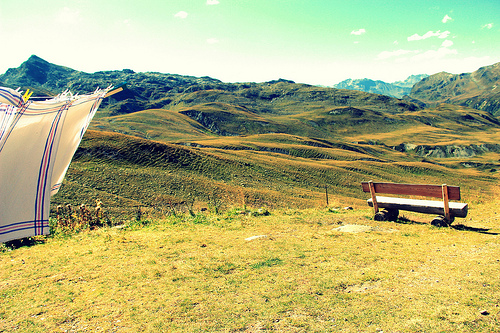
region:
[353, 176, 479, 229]
Wood bench in the field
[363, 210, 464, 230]
Wheels of wood bench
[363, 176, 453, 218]
Stick Two sticks holding back of bench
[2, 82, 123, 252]
Blanket holding from a string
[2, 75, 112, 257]
Blanket has red and blue stripes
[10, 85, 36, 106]
Yellow clothespin holding the blanket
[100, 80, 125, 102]
Brown clothespin holding the blanket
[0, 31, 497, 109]
Mountains in the background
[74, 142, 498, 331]
Green grass in the field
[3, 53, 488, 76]
Part of the sky is white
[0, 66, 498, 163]
grassy mountains in the background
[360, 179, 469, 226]
bench is made of wood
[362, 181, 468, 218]
bench in middle of grassy field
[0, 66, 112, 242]
cloths hanging from clothing line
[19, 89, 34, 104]
yellow clothing pin on line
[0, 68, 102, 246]
cloths are red, white and blue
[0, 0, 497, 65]
sky appear to be green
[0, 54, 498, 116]
mountains covered in moss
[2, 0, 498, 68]
sky is partly cloudy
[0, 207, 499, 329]
parched field of grass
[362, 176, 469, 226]
wooden bench sitting in grass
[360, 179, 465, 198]
back rest of wooden bench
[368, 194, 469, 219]
seat of wooden bench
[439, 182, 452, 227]
right back support on bench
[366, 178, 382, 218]
left back support of bench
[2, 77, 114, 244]
laundry hanging on a line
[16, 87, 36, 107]
yellow clothes pin on laundry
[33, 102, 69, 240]
blue and pink vertical stripes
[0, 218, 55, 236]
lower blue and pink horizontal stripes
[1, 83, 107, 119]
upper blue and pink stripes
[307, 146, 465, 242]
wooden bench on hill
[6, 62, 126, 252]
fabric blowing in breeze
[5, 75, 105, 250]
towels pinned to clothesline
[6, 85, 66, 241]
red and blue stripes around border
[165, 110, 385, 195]
rolling hills and gentle slopes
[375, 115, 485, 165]
semicircular outcrop of light and dark grey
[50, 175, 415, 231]
fencing along side of hill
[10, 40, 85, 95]
tall and jagged peak on mountain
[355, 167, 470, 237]
plank of wood used for bench back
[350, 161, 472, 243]
two short logs supporting bench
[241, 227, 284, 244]
white spot on ground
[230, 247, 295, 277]
small patch of green grass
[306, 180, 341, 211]
small black fence post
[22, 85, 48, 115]
yellow clothes pin on line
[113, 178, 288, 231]
small chain link fence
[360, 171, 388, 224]
large post on bench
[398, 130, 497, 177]
large rock cluster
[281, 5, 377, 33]
beautiful green skies overhead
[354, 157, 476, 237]
long park beach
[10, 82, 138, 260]
red, white and blue tablecloth on clothes line